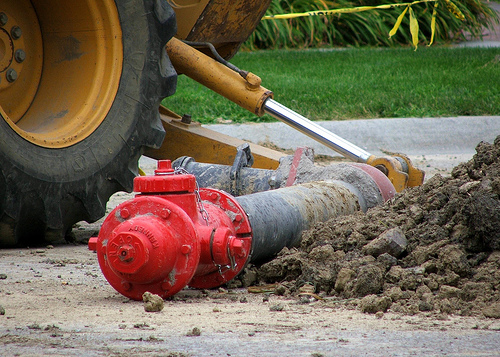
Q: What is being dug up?
A: A fire hydrant.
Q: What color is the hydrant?
A: Red.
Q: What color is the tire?
A: Black.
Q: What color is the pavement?
A: Gray.